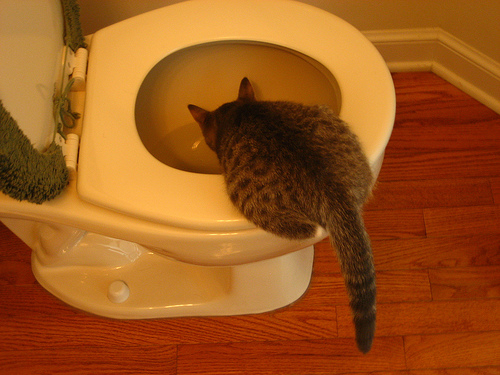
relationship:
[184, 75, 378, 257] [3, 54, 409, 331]
cat in toilet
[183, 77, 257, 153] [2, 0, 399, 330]
head in toilet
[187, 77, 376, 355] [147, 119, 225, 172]
cat drinking water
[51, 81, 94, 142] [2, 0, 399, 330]
string on toilet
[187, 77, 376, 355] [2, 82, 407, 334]
cat on toilet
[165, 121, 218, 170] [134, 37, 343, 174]
water in bowl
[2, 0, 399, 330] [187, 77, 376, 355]
toilet beneath cat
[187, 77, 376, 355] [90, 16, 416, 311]
cat on toilet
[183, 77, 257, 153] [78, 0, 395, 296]
head in toilet bowl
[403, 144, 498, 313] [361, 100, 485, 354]
wood on floor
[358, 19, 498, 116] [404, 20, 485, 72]
white trim on wall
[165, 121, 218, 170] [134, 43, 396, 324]
water in bowl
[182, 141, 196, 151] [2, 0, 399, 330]
glare in toilet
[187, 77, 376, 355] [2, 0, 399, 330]
cat peering into toilet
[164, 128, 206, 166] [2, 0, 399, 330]
water in toilet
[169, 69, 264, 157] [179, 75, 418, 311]
head of cat